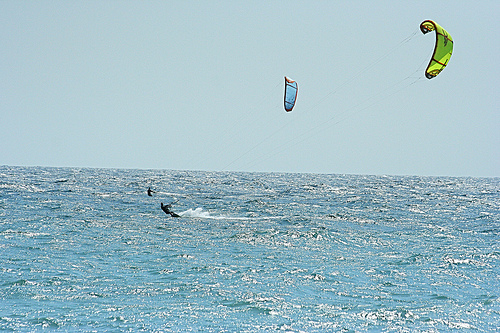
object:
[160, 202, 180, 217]
man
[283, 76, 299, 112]
blue kite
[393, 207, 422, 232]
ground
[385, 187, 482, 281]
surface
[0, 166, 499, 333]
ocean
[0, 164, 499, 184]
horizon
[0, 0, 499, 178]
clear sky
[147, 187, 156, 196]
man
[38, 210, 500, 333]
water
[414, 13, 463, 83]
elephant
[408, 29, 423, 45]
strings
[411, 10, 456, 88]
kite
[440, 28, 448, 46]
design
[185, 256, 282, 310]
light